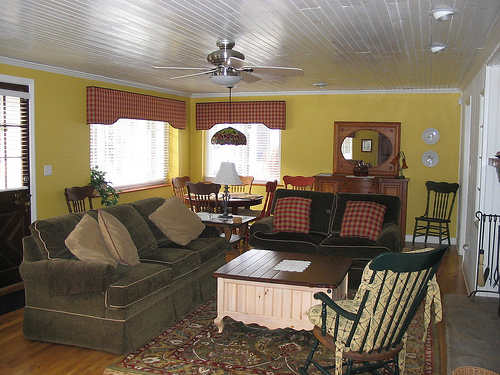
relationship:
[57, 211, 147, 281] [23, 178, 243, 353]
pillows are on top of couch